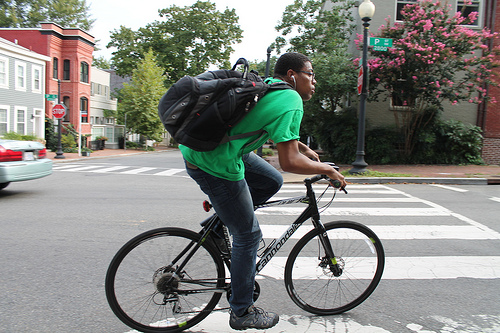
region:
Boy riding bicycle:
[103, 50, 385, 331]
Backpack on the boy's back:
[156, 58, 293, 153]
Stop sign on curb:
[50, 99, 65, 161]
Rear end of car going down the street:
[0, 138, 53, 199]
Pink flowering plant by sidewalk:
[361, 0, 498, 161]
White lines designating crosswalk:
[223, 174, 498, 281]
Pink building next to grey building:
[0, 18, 96, 158]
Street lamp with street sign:
[349, 0, 391, 174]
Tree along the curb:
[114, 46, 166, 149]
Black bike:
[104, 156, 387, 331]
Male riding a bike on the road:
[98, 47, 388, 331]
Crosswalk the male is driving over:
[215, 179, 498, 327]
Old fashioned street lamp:
[345, 1, 378, 180]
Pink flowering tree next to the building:
[363, 4, 497, 167]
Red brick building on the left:
[0, 14, 95, 158]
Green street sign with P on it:
[365, 32, 396, 56]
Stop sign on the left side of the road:
[47, 101, 68, 122]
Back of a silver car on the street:
[0, 125, 57, 191]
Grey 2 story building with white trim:
[0, 36, 53, 152]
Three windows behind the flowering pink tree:
[388, 1, 486, 116]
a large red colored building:
[2, 26, 91, 153]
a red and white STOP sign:
[53, 102, 65, 117]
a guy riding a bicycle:
[104, 50, 384, 330]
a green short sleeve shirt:
[179, 78, 298, 178]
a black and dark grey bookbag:
[162, 51, 290, 151]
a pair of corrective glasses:
[286, 64, 317, 80]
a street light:
[355, 3, 375, 175]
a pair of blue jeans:
[182, 154, 284, 314]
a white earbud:
[287, 73, 297, 85]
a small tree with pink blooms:
[355, 1, 497, 165]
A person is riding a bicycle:
[20, 15, 460, 330]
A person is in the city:
[41, 46, 421, 327]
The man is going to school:
[50, 13, 420, 329]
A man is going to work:
[15, 17, 457, 328]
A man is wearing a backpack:
[32, 12, 482, 330]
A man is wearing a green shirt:
[58, 35, 445, 330]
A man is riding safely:
[50, 20, 446, 330]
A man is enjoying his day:
[26, 17, 447, 314]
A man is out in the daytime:
[55, 30, 440, 320]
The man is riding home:
[22, 1, 443, 325]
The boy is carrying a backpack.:
[151, 56, 261, 145]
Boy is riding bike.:
[141, 154, 374, 319]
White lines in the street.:
[346, 195, 478, 287]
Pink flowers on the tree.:
[398, 15, 453, 90]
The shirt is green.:
[242, 74, 309, 160]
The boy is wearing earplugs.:
[282, 71, 297, 96]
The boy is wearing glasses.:
[303, 65, 322, 82]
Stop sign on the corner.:
[47, 96, 72, 167]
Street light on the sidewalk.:
[349, 3, 386, 181]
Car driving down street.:
[4, 127, 66, 186]